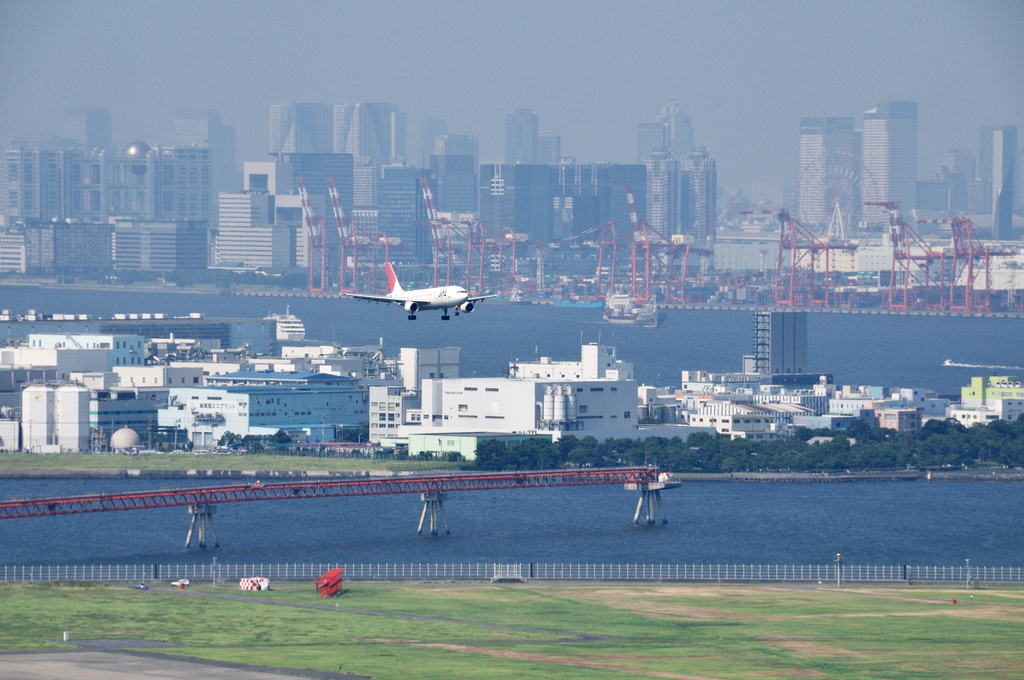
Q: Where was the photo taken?
A: In the air.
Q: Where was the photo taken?
A: At an airport.